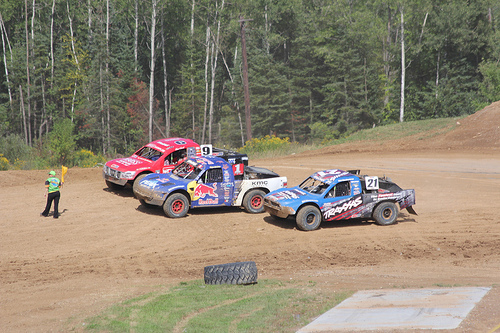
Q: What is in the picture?
A: Three racing trucks.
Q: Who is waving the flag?
A: A person with a green hat.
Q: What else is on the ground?
A: A big tire.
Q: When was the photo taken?
A: Daytime.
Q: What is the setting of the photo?
A: A truck race.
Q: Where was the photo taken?
A: Outdoors near a forest.